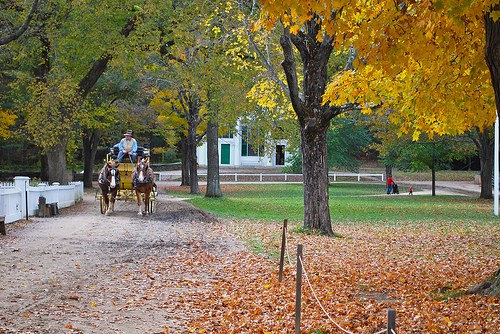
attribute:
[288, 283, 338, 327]
chain — silver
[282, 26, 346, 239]
trunk — large, brown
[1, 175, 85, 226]
picket fence — white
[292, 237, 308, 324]
pole — black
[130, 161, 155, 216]
horse — white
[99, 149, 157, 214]
carriage — wooden, yellow